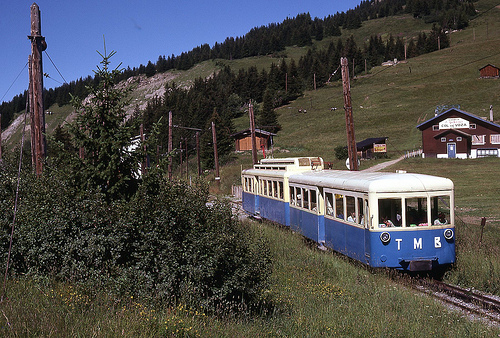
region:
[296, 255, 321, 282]
green grass is growing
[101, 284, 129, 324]
green grass is growing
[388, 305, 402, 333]
green grass is growing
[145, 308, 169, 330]
green grass is growing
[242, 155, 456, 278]
the blue and white passenger train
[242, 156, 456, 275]
the white letter M on the train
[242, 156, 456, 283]
the white letter B on the train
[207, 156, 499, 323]
the train on the track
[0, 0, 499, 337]
the train in the countryside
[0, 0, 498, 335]
the blue sky above the train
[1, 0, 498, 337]
the grass around the train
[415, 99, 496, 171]
the house is brown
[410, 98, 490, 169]
the house is brown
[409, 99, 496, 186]
the house is brown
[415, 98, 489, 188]
the house is brown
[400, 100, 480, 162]
the house is brown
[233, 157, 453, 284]
the train is old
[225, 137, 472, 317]
the train is old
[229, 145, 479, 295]
the train is old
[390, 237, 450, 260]
the letters are white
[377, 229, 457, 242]
headlights on the train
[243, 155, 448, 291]
train on the tracks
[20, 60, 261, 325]
post behind the bushes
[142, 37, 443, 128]
trees on the hill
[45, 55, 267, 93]
trees on the cliff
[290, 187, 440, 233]
people on the train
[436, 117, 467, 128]
banner on the building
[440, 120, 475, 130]
the banner is white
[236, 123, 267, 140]
roof on the shed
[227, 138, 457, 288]
a train on teh tracks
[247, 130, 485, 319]
an old train on tracks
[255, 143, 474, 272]
a passenger train on tracks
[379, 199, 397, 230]
a window on train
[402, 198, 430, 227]
a window on train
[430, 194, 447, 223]
a window on train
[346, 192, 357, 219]
a window on train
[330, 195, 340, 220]
a window on train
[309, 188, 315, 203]
a window on train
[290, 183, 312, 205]
a window on train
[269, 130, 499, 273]
a train on the track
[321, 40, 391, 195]
a tall wooden pole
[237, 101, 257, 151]
a tall wooden pole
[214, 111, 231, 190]
a tall wooden pole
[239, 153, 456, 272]
Rectangular shaped train in royal blue and white.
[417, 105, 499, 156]
Small dark brown house with grey door.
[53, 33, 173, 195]
Fir tree with pointed top branch.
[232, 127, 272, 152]
Small clay-colored house with dark roof.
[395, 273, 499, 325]
Dark brown grooved train tracks.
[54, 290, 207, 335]
Small yellow wildflowers growing in grass.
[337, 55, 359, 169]
Grooved wooden pole above train.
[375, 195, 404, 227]
glass window on the blue train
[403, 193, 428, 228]
glass window on the blue train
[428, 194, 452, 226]
glass window on the blue train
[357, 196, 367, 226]
glass window on the blue train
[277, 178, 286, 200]
glass window on the blue train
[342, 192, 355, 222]
glass window on the blue train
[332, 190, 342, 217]
glass window on the blue train